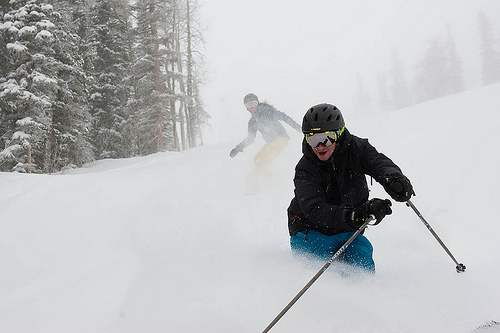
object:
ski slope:
[5, 45, 498, 329]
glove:
[355, 197, 390, 229]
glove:
[385, 172, 412, 204]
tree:
[174, 0, 203, 157]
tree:
[414, 30, 469, 103]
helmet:
[304, 103, 340, 132]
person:
[292, 106, 387, 259]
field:
[0, 88, 480, 329]